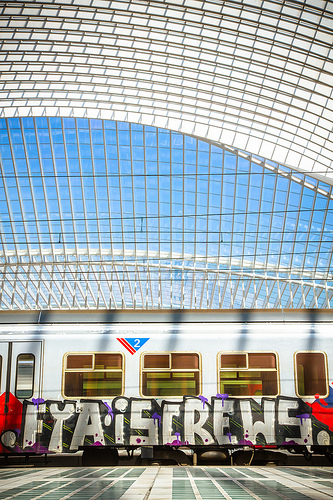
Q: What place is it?
A: It is a train station.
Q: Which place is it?
A: It is a train station.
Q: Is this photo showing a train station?
A: Yes, it is showing a train station.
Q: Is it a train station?
A: Yes, it is a train station.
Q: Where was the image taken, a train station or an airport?
A: It was taken at a train station.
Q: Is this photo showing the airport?
A: No, the picture is showing the train station.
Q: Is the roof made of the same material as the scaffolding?
A: No, the roof is made of glass and the scaffolding is made of metal.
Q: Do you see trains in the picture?
A: Yes, there is a train.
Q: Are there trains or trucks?
A: Yes, there is a train.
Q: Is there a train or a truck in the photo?
A: Yes, there is a train.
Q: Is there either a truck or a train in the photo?
A: Yes, there is a train.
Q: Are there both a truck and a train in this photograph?
A: No, there is a train but no trucks.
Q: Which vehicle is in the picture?
A: The vehicle is a train.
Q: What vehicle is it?
A: The vehicle is a train.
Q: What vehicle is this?
A: This is a train.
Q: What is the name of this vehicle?
A: This is a train.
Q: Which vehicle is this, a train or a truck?
A: This is a train.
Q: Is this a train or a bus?
A: This is a train.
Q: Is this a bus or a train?
A: This is a train.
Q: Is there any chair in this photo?
A: No, there are no chairs.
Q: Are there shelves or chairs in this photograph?
A: No, there are no chairs or shelves.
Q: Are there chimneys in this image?
A: No, there are no chimneys.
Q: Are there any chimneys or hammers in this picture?
A: No, there are no chimneys or hammers.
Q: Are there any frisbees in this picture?
A: No, there are no frisbees.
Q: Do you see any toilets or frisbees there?
A: No, there are no frisbees or toilets.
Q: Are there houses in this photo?
A: No, there are no houses.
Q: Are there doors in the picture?
A: Yes, there is a door.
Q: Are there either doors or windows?
A: Yes, there is a door.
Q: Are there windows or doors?
A: Yes, there is a door.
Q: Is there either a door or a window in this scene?
A: Yes, there is a door.